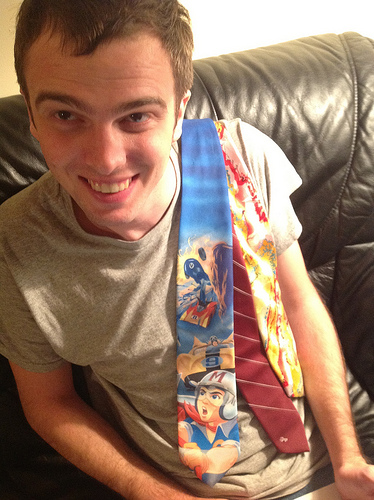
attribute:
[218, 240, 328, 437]
tie — red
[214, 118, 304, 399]
tie — print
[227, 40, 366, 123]
leather seating — black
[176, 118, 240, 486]
tie — blue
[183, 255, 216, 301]
bird — blue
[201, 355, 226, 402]
letter "m" — red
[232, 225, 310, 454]
tie — maroon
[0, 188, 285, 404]
shirt — cotton